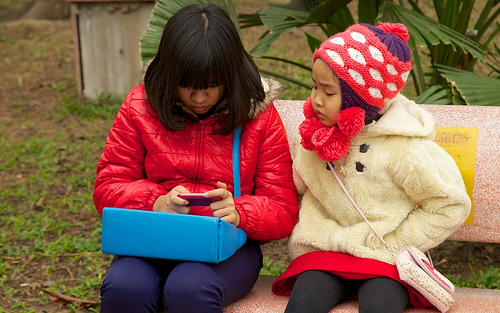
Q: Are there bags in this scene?
A: Yes, there is a bag.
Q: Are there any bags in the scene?
A: Yes, there is a bag.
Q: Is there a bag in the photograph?
A: Yes, there is a bag.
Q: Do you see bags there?
A: Yes, there is a bag.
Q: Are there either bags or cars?
A: Yes, there is a bag.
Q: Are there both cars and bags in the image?
A: No, there is a bag but no cars.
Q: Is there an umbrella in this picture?
A: No, there are no umbrellas.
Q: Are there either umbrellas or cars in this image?
A: No, there are no umbrellas or cars.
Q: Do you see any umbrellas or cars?
A: No, there are no umbrellas or cars.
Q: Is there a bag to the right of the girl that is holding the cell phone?
A: Yes, there is a bag to the right of the girl.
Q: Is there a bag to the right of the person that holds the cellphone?
A: Yes, there is a bag to the right of the girl.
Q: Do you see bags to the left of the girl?
A: No, the bag is to the right of the girl.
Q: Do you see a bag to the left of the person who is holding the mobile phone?
A: No, the bag is to the right of the girl.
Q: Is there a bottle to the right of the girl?
A: No, there is a bag to the right of the girl.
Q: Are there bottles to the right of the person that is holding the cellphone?
A: No, there is a bag to the right of the girl.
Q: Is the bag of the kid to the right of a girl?
A: Yes, the bag is to the right of a girl.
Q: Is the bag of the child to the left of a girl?
A: No, the bag is to the right of a girl.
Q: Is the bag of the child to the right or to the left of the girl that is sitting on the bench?
A: The bag is to the right of the girl.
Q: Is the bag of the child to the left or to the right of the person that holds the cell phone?
A: The bag is to the right of the girl.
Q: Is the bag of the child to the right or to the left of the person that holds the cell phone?
A: The bag is to the right of the girl.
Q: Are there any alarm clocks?
A: No, there are no alarm clocks.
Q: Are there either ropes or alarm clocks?
A: No, there are no alarm clocks or ropes.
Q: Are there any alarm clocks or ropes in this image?
A: No, there are no alarm clocks or ropes.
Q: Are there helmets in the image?
A: No, there are no helmets.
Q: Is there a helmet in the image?
A: No, there are no helmets.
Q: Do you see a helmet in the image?
A: No, there are no helmets.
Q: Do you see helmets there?
A: No, there are no helmets.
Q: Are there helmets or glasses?
A: No, there are no helmets or glasses.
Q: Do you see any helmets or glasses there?
A: No, there are no helmets or glasses.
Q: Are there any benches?
A: Yes, there is a bench.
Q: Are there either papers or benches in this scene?
A: Yes, there is a bench.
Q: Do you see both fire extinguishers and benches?
A: No, there is a bench but no fire extinguishers.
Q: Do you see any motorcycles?
A: No, there are no motorcycles.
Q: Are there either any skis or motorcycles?
A: No, there are no motorcycles or skis.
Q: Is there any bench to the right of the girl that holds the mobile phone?
A: Yes, there is a bench to the right of the girl.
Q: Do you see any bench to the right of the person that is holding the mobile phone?
A: Yes, there is a bench to the right of the girl.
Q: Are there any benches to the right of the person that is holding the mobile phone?
A: Yes, there is a bench to the right of the girl.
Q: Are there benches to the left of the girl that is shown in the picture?
A: No, the bench is to the right of the girl.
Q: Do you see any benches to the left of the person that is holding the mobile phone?
A: No, the bench is to the right of the girl.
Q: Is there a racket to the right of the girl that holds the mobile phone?
A: No, there is a bench to the right of the girl.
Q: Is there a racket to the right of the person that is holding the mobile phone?
A: No, there is a bench to the right of the girl.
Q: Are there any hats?
A: Yes, there is a hat.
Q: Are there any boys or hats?
A: Yes, there is a hat.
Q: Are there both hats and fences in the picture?
A: No, there is a hat but no fences.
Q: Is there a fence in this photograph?
A: No, there are no fences.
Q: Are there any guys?
A: No, there are no guys.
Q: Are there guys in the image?
A: No, there are no guys.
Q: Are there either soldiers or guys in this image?
A: No, there are no guys or soldiers.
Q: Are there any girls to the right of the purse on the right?
A: No, the girl is to the left of the purse.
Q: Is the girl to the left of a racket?
A: No, the girl is to the left of the purse.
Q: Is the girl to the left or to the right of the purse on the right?
A: The girl is to the left of the purse.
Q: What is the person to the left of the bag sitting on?
A: The girl is sitting on the bench.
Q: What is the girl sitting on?
A: The girl is sitting on the bench.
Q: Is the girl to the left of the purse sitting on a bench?
A: Yes, the girl is sitting on a bench.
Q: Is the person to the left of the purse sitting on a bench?
A: Yes, the girl is sitting on a bench.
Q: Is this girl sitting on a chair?
A: No, the girl is sitting on a bench.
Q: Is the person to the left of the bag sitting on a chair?
A: No, the girl is sitting on a bench.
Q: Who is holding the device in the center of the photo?
A: The girl is holding the cell phone.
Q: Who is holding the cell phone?
A: The girl is holding the cell phone.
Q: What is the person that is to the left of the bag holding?
A: The girl is holding the cellphone.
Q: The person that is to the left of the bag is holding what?
A: The girl is holding the cellphone.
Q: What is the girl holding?
A: The girl is holding the cellphone.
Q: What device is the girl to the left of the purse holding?
A: The girl is holding the cellphone.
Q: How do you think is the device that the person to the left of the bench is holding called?
A: The device is a cell phone.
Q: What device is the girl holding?
A: The girl is holding the cellphone.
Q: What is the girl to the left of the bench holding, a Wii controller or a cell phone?
A: The girl is holding a cell phone.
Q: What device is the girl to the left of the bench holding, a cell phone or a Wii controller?
A: The girl is holding a cell phone.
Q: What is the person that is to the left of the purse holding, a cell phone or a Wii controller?
A: The girl is holding a cell phone.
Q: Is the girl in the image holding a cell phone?
A: Yes, the girl is holding a cell phone.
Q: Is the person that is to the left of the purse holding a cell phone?
A: Yes, the girl is holding a cell phone.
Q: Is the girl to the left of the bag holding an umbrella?
A: No, the girl is holding a cell phone.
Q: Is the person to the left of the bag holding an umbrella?
A: No, the girl is holding a cell phone.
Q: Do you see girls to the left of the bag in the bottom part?
A: Yes, there is a girl to the left of the bag.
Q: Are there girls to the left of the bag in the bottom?
A: Yes, there is a girl to the left of the bag.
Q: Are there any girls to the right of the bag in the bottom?
A: No, the girl is to the left of the bag.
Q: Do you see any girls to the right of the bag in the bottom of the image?
A: No, the girl is to the left of the bag.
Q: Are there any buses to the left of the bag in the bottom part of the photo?
A: No, there is a girl to the left of the bag.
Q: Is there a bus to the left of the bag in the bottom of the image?
A: No, there is a girl to the left of the bag.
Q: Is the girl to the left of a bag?
A: Yes, the girl is to the left of a bag.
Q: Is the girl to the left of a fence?
A: No, the girl is to the left of a bag.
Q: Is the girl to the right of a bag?
A: No, the girl is to the left of a bag.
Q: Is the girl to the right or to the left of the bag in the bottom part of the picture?
A: The girl is to the left of the bag.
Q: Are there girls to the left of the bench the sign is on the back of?
A: Yes, there is a girl to the left of the bench.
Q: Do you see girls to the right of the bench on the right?
A: No, the girl is to the left of the bench.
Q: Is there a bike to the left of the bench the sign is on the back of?
A: No, there is a girl to the left of the bench.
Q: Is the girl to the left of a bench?
A: Yes, the girl is to the left of a bench.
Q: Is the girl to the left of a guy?
A: No, the girl is to the left of a bench.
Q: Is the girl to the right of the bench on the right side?
A: No, the girl is to the left of the bench.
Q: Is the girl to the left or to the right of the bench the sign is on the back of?
A: The girl is to the left of the bench.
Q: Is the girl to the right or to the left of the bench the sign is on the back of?
A: The girl is to the left of the bench.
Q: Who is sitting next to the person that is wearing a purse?
A: The girl is sitting next to the child.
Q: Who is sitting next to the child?
A: The girl is sitting next to the child.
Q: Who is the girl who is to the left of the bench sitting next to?
A: The girl is sitting next to the kid.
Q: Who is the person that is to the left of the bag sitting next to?
A: The girl is sitting next to the kid.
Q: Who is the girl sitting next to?
A: The girl is sitting next to the kid.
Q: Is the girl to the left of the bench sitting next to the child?
A: Yes, the girl is sitting next to the child.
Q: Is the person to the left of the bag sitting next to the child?
A: Yes, the girl is sitting next to the child.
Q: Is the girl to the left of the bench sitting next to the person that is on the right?
A: Yes, the girl is sitting next to the child.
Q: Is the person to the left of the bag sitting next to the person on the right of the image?
A: Yes, the girl is sitting next to the child.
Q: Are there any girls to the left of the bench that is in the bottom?
A: Yes, there is a girl to the left of the bench.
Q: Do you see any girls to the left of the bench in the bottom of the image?
A: Yes, there is a girl to the left of the bench.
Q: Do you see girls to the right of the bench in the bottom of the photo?
A: No, the girl is to the left of the bench.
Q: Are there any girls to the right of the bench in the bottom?
A: No, the girl is to the left of the bench.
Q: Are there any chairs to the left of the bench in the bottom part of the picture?
A: No, there is a girl to the left of the bench.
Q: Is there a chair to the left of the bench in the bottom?
A: No, there is a girl to the left of the bench.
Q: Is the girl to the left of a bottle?
A: No, the girl is to the left of a bench.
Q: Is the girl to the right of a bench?
A: No, the girl is to the left of a bench.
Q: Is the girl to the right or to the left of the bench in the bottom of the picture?
A: The girl is to the left of the bench.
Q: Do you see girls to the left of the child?
A: Yes, there is a girl to the left of the child.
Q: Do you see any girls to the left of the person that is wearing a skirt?
A: Yes, there is a girl to the left of the child.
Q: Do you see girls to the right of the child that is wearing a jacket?
A: No, the girl is to the left of the kid.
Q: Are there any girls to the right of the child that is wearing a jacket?
A: No, the girl is to the left of the kid.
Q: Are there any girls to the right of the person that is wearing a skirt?
A: No, the girl is to the left of the kid.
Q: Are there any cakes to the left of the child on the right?
A: No, there is a girl to the left of the child.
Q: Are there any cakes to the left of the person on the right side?
A: No, there is a girl to the left of the child.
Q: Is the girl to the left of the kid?
A: Yes, the girl is to the left of the kid.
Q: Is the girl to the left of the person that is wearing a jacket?
A: Yes, the girl is to the left of the kid.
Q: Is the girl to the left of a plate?
A: No, the girl is to the left of the kid.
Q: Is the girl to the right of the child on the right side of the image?
A: No, the girl is to the left of the child.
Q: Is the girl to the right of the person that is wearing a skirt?
A: No, the girl is to the left of the child.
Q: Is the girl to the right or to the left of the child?
A: The girl is to the left of the child.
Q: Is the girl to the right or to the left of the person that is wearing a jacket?
A: The girl is to the left of the child.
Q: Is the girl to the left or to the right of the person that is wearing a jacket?
A: The girl is to the left of the child.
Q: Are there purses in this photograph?
A: Yes, there is a purse.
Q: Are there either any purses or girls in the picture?
A: Yes, there is a purse.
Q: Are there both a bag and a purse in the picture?
A: Yes, there are both a purse and a bag.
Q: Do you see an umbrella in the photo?
A: No, there are no umbrellas.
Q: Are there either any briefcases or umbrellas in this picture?
A: No, there are no umbrellas or briefcases.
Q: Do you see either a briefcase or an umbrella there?
A: No, there are no umbrellas or briefcases.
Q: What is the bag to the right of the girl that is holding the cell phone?
A: The bag is a purse.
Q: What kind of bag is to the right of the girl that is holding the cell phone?
A: The bag is a purse.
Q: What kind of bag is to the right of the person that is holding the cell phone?
A: The bag is a purse.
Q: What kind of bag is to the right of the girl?
A: The bag is a purse.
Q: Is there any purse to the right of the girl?
A: Yes, there is a purse to the right of the girl.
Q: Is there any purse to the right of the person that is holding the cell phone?
A: Yes, there is a purse to the right of the girl.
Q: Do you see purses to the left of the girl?
A: No, the purse is to the right of the girl.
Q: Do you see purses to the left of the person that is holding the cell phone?
A: No, the purse is to the right of the girl.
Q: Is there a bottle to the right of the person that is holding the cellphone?
A: No, there is a purse to the right of the girl.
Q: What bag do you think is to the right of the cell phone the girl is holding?
A: The bag is a purse.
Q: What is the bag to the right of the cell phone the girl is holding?
A: The bag is a purse.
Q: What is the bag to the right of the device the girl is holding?
A: The bag is a purse.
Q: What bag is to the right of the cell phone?
A: The bag is a purse.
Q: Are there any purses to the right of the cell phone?
A: Yes, there is a purse to the right of the cell phone.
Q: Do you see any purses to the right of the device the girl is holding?
A: Yes, there is a purse to the right of the cell phone.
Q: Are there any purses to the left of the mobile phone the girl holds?
A: No, the purse is to the right of the cell phone.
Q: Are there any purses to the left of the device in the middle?
A: No, the purse is to the right of the cell phone.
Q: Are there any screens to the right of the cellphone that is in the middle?
A: No, there is a purse to the right of the mobile phone.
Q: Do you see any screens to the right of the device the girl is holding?
A: No, there is a purse to the right of the mobile phone.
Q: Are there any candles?
A: No, there are no candles.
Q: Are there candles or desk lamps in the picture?
A: No, there are no candles or desk lamps.